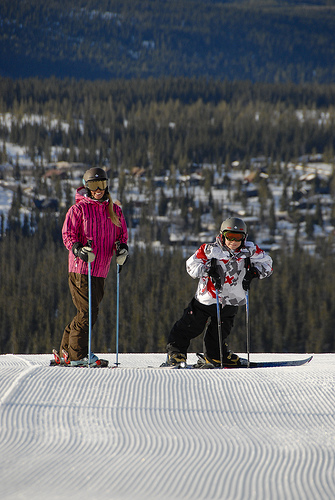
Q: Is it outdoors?
A: Yes, it is outdoors.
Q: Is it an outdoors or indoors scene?
A: It is outdoors.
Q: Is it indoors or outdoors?
A: It is outdoors.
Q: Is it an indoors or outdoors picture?
A: It is outdoors.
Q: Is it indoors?
A: No, it is outdoors.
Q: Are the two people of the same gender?
A: No, they are both male and female.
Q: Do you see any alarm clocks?
A: No, there are no alarm clocks.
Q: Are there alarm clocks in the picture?
A: No, there are no alarm clocks.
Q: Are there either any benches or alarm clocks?
A: No, there are no alarm clocks or benches.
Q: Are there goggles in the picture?
A: Yes, there are goggles.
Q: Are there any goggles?
A: Yes, there are goggles.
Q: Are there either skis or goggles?
A: Yes, there are goggles.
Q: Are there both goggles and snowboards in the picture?
A: No, there are goggles but no snowboards.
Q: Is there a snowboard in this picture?
A: No, there are no snowboards.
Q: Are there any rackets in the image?
A: No, there are no rackets.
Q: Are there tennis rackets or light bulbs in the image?
A: No, there are no tennis rackets or light bulbs.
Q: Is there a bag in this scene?
A: No, there are no bags.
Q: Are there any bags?
A: No, there are no bags.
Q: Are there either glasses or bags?
A: No, there are no bags or glasses.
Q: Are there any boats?
A: No, there are no boats.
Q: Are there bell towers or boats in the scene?
A: No, there are no boats or bell towers.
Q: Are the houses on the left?
A: Yes, the houses are on the left of the image.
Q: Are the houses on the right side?
A: No, the houses are on the left of the image.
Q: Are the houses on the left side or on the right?
A: The houses are on the left of the image.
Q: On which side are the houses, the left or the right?
A: The houses are on the left of the image.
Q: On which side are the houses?
A: The houses are on the left of the image.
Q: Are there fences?
A: No, there are no fences.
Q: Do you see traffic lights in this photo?
A: No, there are no traffic lights.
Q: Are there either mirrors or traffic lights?
A: No, there are no traffic lights or mirrors.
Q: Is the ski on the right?
A: Yes, the ski is on the right of the image.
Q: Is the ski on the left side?
A: No, the ski is on the right of the image.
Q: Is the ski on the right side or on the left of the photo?
A: The ski is on the right of the image.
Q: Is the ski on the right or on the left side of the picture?
A: The ski is on the right of the image.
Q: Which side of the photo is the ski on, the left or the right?
A: The ski is on the right of the image.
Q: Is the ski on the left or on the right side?
A: The ski is on the right of the image.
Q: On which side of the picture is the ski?
A: The ski is on the right of the image.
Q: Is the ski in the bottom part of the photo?
A: Yes, the ski is in the bottom of the image.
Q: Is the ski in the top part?
A: No, the ski is in the bottom of the image.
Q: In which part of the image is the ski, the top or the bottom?
A: The ski is in the bottom of the image.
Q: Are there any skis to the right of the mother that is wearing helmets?
A: Yes, there is a ski to the right of the mom.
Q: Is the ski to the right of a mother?
A: Yes, the ski is to the right of a mother.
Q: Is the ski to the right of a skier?
A: No, the ski is to the right of a mother.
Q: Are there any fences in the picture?
A: No, there are no fences.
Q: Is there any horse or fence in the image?
A: No, there are no fences or horses.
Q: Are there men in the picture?
A: No, there are no men.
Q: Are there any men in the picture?
A: No, there are no men.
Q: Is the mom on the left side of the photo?
A: Yes, the mom is on the left of the image.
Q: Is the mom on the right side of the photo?
A: No, the mom is on the left of the image.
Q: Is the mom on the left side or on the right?
A: The mom is on the left of the image.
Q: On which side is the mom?
A: The mom is on the left of the image.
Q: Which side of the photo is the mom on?
A: The mom is on the left of the image.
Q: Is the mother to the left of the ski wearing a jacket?
A: Yes, the mom is wearing a jacket.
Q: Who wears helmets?
A: The mother wears helmets.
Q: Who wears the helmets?
A: The mother wears helmets.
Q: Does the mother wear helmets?
A: Yes, the mother wears helmets.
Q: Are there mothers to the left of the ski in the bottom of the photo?
A: Yes, there is a mother to the left of the ski.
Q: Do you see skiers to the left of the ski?
A: No, there is a mother to the left of the ski.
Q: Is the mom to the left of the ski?
A: Yes, the mom is to the left of the ski.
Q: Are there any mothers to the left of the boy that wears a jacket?
A: Yes, there is a mother to the left of the boy.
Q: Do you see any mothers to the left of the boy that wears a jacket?
A: Yes, there is a mother to the left of the boy.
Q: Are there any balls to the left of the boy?
A: No, there is a mother to the left of the boy.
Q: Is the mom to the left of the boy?
A: Yes, the mom is to the left of the boy.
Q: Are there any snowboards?
A: No, there are no snowboards.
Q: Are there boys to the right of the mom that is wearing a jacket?
A: Yes, there is a boy to the right of the mom.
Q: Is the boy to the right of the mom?
A: Yes, the boy is to the right of the mom.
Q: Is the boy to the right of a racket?
A: No, the boy is to the right of the mom.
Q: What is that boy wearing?
A: The boy is wearing a jacket.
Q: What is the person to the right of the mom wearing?
A: The boy is wearing a jacket.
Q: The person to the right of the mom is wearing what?
A: The boy is wearing a jacket.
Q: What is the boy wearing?
A: The boy is wearing a jacket.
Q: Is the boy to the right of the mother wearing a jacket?
A: Yes, the boy is wearing a jacket.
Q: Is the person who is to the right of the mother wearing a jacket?
A: Yes, the boy is wearing a jacket.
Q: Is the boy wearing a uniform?
A: No, the boy is wearing a jacket.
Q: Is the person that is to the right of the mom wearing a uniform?
A: No, the boy is wearing a jacket.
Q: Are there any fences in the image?
A: No, there are no fences.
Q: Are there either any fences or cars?
A: No, there are no fences or cars.